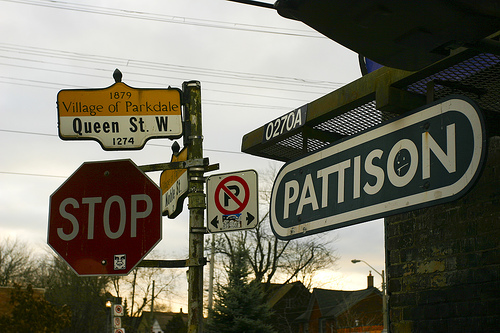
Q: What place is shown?
A: It is a village.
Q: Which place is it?
A: It is a village.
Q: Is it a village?
A: Yes, it is a village.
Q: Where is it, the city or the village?
A: It is the village.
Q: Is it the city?
A: No, it is the village.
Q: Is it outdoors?
A: Yes, it is outdoors.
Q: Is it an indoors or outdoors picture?
A: It is outdoors.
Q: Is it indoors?
A: No, it is outdoors.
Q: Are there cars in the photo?
A: No, there are no cars.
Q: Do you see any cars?
A: No, there are no cars.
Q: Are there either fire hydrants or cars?
A: No, there are no cars or fire hydrants.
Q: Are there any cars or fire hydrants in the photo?
A: No, there are no cars or fire hydrants.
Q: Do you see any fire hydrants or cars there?
A: No, there are no cars or fire hydrants.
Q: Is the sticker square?
A: Yes, the sticker is square.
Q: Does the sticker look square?
A: Yes, the sticker is square.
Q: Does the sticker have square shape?
A: Yes, the sticker is square.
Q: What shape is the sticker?
A: The sticker is square.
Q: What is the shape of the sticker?
A: The sticker is square.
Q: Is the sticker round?
A: No, the sticker is square.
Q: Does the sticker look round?
A: No, the sticker is square.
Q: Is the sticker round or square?
A: The sticker is square.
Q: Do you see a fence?
A: No, there are no fences.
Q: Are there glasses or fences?
A: No, there are no fences or glasses.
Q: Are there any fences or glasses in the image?
A: No, there are no fences or glasses.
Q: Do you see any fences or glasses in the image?
A: No, there are no fences or glasses.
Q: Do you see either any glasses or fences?
A: No, there are no fences or glasses.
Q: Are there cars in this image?
A: No, there are no cars.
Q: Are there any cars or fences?
A: No, there are no cars or fences.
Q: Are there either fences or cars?
A: No, there are no cars or fences.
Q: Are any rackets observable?
A: No, there are no rackets.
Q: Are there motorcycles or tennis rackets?
A: No, there are no tennis rackets or motorcycles.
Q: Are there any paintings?
A: No, there are no paintings.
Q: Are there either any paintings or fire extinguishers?
A: No, there are no paintings or fire extinguishers.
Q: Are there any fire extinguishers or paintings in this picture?
A: No, there are no paintings or fire extinguishers.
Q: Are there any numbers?
A: Yes, there are numbers.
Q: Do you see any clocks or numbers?
A: Yes, there are numbers.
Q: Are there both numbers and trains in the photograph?
A: No, there are numbers but no trains.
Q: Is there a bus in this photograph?
A: No, there are no buses.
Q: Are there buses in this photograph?
A: No, there are no buses.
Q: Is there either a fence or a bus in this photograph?
A: No, there are no buses or fences.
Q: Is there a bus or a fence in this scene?
A: No, there are no buses or fences.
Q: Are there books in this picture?
A: No, there are no books.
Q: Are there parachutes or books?
A: No, there are no books or parachutes.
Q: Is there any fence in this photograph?
A: No, there are no fences.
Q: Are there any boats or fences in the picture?
A: No, there are no fences or boats.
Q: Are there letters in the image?
A: Yes, there are letters.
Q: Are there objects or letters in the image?
A: Yes, there are letters.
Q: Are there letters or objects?
A: Yes, there are letters.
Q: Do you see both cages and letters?
A: No, there are letters but no cages.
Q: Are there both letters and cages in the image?
A: No, there are letters but no cages.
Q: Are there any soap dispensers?
A: No, there are no soap dispensers.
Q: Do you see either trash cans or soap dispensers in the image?
A: No, there are no soap dispensers or trash cans.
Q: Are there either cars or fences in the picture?
A: No, there are no fences or cars.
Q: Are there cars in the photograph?
A: No, there are no cars.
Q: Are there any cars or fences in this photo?
A: No, there are no cars or fences.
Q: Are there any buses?
A: No, there are no buses.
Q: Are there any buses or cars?
A: No, there are no buses or cars.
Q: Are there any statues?
A: No, there are no statues.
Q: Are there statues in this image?
A: No, there are no statues.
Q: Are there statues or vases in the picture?
A: No, there are no statues or vases.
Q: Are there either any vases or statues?
A: No, there are no statues or vases.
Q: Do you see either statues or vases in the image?
A: No, there are no statues or vases.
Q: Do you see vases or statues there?
A: No, there are no statues or vases.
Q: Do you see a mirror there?
A: No, there are no mirrors.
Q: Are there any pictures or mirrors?
A: No, there are no mirrors or pictures.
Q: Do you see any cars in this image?
A: No, there are no cars.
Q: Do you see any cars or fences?
A: No, there are no cars or fences.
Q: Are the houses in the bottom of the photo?
A: Yes, the houses are in the bottom of the image.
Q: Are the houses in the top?
A: No, the houses are in the bottom of the image.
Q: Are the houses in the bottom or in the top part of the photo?
A: The houses are in the bottom of the image.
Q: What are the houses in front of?
A: The houses are in front of the trees.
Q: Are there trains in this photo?
A: No, there are no trains.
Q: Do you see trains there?
A: No, there are no trains.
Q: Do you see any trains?
A: No, there are no trains.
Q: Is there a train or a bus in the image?
A: No, there are no trains or buses.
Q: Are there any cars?
A: No, there are no cars.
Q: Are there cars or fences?
A: No, there are no cars or fences.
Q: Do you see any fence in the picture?
A: No, there are no fences.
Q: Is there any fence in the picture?
A: No, there are no fences.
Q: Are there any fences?
A: No, there are no fences.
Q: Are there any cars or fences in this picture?
A: No, there are no fences or cars.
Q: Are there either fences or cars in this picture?
A: No, there are no fences or cars.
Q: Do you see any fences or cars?
A: No, there are no fences or cars.